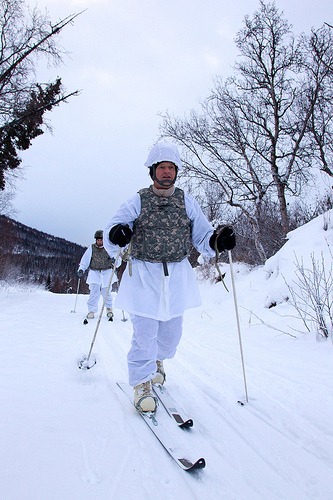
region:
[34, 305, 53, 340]
white snow on the path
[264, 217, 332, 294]
tall mound of snow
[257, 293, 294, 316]
small hole in the snow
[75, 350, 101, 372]
round bottom of ski pole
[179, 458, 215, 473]
curved edge of snow ski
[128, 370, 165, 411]
brown boot on skier's foot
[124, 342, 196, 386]
frayed edge on blue jeans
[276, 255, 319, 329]
tree branches coming out of the snow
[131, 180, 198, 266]
black and brown vest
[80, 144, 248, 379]
skier's walking on the path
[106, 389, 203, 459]
these are two skis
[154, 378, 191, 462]
the skis are white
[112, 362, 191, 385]
these are two shoes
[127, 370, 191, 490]
the shoes are tan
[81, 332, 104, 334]
this is a ski pole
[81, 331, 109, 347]
the pole is metal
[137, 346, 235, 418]
these are white pants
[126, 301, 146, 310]
this is a white shirt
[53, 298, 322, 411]
there are two poles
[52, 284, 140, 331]
this is another man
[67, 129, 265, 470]
two soldiers on skis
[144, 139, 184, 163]
the helmet of a soldier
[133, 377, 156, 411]
the boot of a soldier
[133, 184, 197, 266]
the vest of a soldier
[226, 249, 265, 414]
a long white ski pole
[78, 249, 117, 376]
a long white ski pole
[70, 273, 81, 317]
a long white ski pole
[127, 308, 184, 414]
the legs of a man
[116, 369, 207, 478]
two white and black snow skis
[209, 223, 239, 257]
a black ski glove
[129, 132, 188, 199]
man's hat is white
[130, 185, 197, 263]
man wearing a vest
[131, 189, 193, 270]
vest color is camouflage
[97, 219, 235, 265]
man is wearing gloves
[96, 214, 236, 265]
man's gloves are black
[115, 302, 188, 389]
man's pants are white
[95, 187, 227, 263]
man's shirt is white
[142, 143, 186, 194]
man's helmet strapped to face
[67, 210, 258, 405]
man holding ski poles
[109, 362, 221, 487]
man standing on skis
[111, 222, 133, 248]
Black glove on a man's right hand.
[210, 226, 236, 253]
Black glove on a man's left hand.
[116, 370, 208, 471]
Long white and brown skis with black bottoms on a man out front.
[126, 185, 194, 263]
A camo protective vest on the first man's chest.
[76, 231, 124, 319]
A man in all white and camo vest in the rear.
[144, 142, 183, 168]
A white cover over a soldiers helmet.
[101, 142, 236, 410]
A soldier with a camo vest on and white helmet cover.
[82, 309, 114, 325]
Skis on the man behind the first man.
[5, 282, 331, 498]
White snow down the trail the men are skiing on.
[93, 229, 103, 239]
Camo helmet on the man behind.